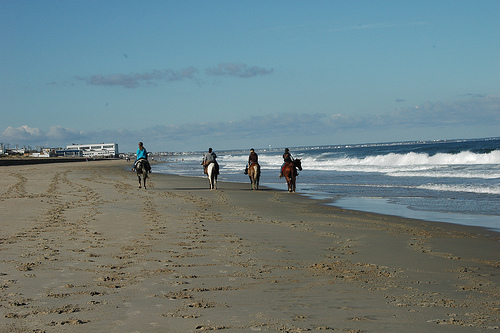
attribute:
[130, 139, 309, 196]
horses — together, walking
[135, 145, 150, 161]
jacket — blue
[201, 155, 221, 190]
horse — white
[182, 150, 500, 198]
waves — crashing, white, breaking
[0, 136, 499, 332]
beach — clumpy, wet, tan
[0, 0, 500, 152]
sky — blue, clear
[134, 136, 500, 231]
surf — spraying, blue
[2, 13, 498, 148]
clouds — gray, white